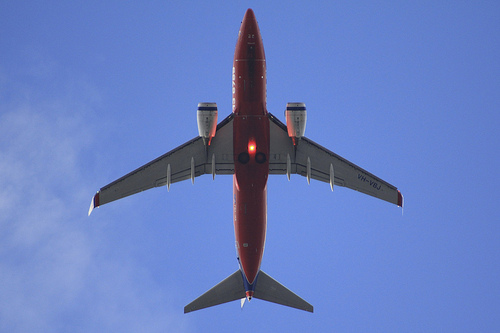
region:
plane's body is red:
[207, 8, 281, 317]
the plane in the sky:
[87, 28, 414, 320]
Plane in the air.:
[53, 0, 408, 325]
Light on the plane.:
[224, 123, 292, 192]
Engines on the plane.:
[176, 79, 354, 159]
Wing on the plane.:
[260, 97, 496, 242]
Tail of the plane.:
[138, 267, 368, 325]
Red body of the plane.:
[210, 14, 346, 318]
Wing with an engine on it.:
[63, 121, 238, 242]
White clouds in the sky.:
[33, 75, 197, 214]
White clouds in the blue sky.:
[10, 64, 157, 234]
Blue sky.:
[10, 39, 257, 322]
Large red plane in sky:
[85, 6, 405, 316]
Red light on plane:
[245, 137, 257, 154]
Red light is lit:
[247, 140, 255, 154]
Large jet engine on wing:
[195, 98, 217, 141]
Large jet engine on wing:
[285, 101, 307, 141]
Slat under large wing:
[165, 162, 170, 192]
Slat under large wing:
[188, 155, 195, 185]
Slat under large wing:
[209, 152, 217, 178]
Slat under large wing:
[283, 150, 291, 180]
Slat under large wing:
[304, 156, 313, 186]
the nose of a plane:
[196, 4, 338, 81]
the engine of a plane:
[153, 93, 240, 182]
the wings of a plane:
[66, 138, 424, 223]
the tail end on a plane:
[181, 236, 358, 323]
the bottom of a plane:
[211, 77, 342, 252]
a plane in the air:
[160, 70, 385, 287]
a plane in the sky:
[36, 15, 423, 252]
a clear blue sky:
[322, 223, 422, 292]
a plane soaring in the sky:
[88, 24, 437, 252]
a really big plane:
[78, 48, 424, 270]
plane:
[108, 12, 402, 332]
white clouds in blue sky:
[45, 46, 106, 96]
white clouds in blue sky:
[337, 243, 382, 297]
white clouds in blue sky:
[428, 242, 479, 289]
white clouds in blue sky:
[274, 205, 351, 250]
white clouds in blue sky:
[385, 81, 443, 129]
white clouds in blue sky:
[342, 42, 399, 112]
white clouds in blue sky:
[125, 228, 183, 278]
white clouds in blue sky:
[58, 281, 116, 322]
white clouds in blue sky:
[64, 142, 85, 199]